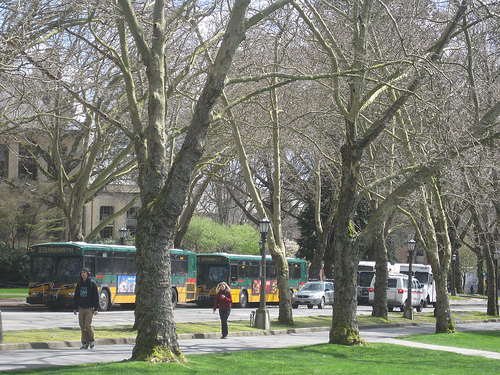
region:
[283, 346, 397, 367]
the grass is green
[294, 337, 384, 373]
the grass is short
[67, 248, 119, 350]
the man is walking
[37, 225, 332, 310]
the buses are parked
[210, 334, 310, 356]
the sidewalk is gray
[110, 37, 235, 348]
the tree has no leaves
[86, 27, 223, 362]
the tree is brown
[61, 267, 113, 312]
the jacket is blue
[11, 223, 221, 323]
the bus is green and yellow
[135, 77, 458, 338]
there are many trees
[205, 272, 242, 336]
woman in a red jacket with long blonde hair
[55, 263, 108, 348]
man with khaki pants with a black sweater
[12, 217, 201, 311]
green and yellow passenger bus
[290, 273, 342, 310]
silver and grey suv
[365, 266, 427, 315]
white van with a red and black stripe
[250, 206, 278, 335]
black lamp post with a white glass top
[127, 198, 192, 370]
brown tree trunk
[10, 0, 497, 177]
leafless brown tree limbs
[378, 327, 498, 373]
trim green grass split by a grey sidewalk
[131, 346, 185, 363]
green moss growing on a brown tree trunk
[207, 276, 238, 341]
A woman checking her cell phone.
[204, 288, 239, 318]
A red jacket being worn by the woman.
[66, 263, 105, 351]
A man walking on the side walk.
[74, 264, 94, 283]
Head phones being worn by the man.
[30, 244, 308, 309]
Two green and yellow buses parked on the street.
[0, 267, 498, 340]
A street with several vehicles on it.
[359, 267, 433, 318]
A white van driving down the road.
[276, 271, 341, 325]
A silver car going around the buses.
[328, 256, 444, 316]
A pair of white trucks on the street.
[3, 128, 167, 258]
A tan building with many windows.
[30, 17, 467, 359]
A suburban street scene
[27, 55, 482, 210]
A thicket of leafless trees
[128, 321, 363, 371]
Two tree trunks and a patch of lawn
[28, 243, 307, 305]
Two buses parked on a street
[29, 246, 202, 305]
A bus parked on a street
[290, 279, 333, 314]
A silver car driving on a street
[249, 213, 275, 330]
A street light with antique design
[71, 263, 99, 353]
A man in a blue hoodie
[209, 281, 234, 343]
A woman in a red sweater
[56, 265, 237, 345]
Two people walking on a street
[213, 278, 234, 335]
this is a woman walking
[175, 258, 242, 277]
these are two buses parked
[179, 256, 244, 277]
the buses are green in color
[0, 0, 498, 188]
the trees are branchy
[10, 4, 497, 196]
the branches are dry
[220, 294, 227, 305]
the jacket is red in color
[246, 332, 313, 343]
the path is clean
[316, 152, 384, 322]
the tree is big in size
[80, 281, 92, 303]
the jamper is black in color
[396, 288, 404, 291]
the rear light is on